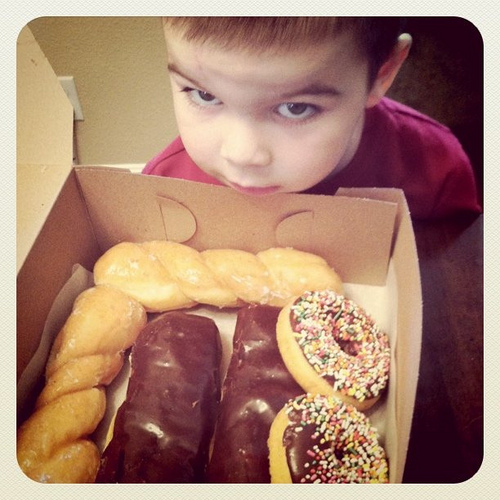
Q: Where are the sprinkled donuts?
A: On the right side.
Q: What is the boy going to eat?
A: Donuts.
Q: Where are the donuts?
A: In the cardboard box.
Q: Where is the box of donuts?
A: On a dark brown table.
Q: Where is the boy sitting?
A: At the dining table.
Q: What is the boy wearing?
A: A red shirt.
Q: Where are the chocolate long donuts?
A: In the middle of the box.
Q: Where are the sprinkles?
A: On the doughnuts.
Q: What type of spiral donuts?
A: Glazed.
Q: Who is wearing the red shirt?
A: The boy.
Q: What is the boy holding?
A: Donut box.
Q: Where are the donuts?
A: In the box.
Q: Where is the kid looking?
A: Up.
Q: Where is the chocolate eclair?
A: In the box.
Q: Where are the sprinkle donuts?
A: In the box.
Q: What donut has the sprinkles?
A: The chocolate donuts.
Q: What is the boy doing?
A: Looking up.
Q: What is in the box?
A: Donuts.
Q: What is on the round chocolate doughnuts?
A: Sprinkles.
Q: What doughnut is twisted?
A: The white frosted one.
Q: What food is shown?
A: Doughnuts.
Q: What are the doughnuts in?
A: Box.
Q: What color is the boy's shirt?
A: Red.